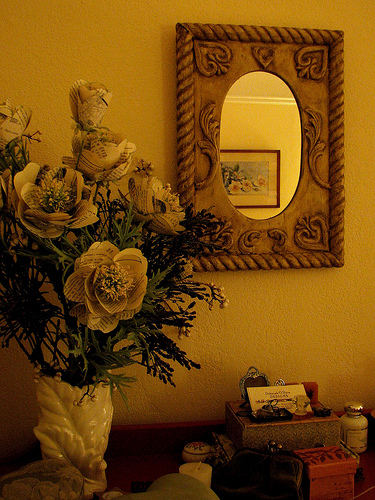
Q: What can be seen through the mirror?
A: Floral picture.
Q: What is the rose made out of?
A: Newspaper.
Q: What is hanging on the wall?
A: A decorative mirror.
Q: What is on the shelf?
A: Knick knacks.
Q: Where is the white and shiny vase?
A: On the table.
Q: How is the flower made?
A: It is made out newspaper.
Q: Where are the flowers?
A: In the vase.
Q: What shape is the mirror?
A: It is oval.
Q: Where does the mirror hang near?
A: The vase of flowers.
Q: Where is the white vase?
A: On the dresser.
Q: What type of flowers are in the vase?
A: Artificial.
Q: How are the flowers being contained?
A: In a vase.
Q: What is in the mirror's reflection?
A: A picture.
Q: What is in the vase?
A: Flowers.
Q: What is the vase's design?
A: Leaves.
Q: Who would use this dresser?
A: A woman.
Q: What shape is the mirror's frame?
A: Rectangle.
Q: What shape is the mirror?
A: Oval.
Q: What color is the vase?
A: White.